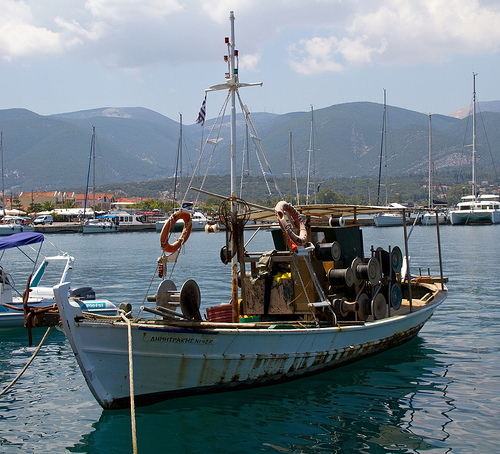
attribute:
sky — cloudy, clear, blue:
[1, 2, 500, 123]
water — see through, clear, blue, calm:
[0, 224, 500, 452]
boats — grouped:
[1, 69, 500, 453]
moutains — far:
[1, 99, 500, 177]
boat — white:
[449, 73, 500, 228]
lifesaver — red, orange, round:
[157, 211, 193, 253]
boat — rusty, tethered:
[54, 10, 448, 412]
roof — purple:
[1, 231, 45, 249]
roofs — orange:
[0, 191, 155, 206]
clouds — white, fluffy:
[0, 1, 500, 75]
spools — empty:
[317, 239, 402, 325]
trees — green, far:
[82, 166, 473, 208]